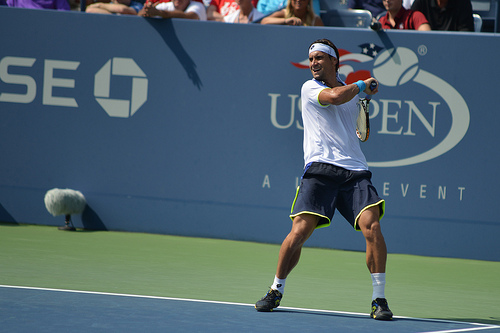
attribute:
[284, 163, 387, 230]
shorts — blue, disheveled, tennis, here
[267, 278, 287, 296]
sock — white, athletic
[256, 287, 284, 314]
sneaker — black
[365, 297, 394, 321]
sneaker — black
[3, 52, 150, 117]
word — white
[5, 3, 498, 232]
background — blue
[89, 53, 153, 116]
octagon — white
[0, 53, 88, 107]
letters — bold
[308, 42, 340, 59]
headband — white, athletic, here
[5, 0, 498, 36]
spectators — sitting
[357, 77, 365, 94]
band — blue, light, athletic, wrist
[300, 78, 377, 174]
tee shirt — white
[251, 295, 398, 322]
shoes — blue, tennis, colored, dark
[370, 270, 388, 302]
sock — white, athletic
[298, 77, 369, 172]
top — white, athletic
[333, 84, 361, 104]
quadriceps — muscular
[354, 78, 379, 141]
racket — tennis, swinging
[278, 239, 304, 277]
calf — muscular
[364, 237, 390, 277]
calf — muscular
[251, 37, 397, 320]
player — male, tennis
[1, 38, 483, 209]
advertising — behind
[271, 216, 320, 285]
leg — muscular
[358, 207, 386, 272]
leg — muscular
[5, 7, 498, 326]
court — tennis, green, blue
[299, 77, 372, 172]
t-shirt — white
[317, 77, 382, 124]
arms — brown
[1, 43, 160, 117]
logo — chase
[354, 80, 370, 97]
armband — blue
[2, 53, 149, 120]
sponsor — corporate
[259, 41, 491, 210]
name — written